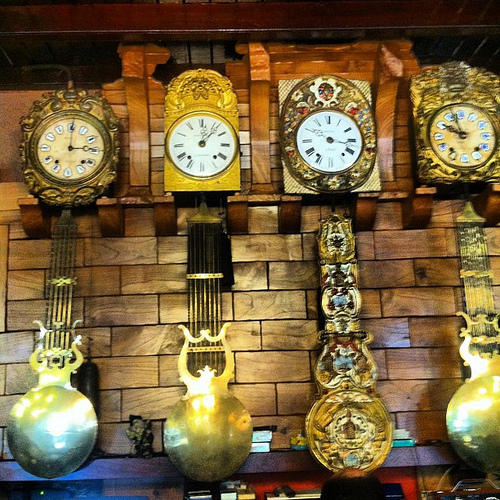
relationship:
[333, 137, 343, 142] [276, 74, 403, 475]
short hand of clock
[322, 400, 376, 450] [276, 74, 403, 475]
images on clock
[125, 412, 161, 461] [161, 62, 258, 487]
figure next to clock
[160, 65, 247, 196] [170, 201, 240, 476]
clock has pendulum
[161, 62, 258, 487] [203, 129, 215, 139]
clock has arm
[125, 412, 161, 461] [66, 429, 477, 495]
figure on shelf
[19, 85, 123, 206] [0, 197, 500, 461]
clock face on wall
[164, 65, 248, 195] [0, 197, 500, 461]
clock on wall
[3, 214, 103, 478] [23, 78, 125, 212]
pendulum hanging from clock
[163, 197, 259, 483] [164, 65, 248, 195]
pendulum hanging from clock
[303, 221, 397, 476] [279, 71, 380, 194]
pendulum hanging from clock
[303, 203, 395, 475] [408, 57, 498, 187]
pendulum hanging from clock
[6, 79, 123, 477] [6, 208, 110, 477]
clock has pendulum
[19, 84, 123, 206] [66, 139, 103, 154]
clock face has black hands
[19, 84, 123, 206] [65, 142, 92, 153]
clock face has hand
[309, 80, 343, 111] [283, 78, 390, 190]
gemstones on clock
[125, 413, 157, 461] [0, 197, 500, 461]
figure on wall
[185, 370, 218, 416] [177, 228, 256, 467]
spot on pendulum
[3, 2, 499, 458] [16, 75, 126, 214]
wall behind clock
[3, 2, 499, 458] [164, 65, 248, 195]
wall behind clock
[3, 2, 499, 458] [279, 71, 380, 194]
wall behind clock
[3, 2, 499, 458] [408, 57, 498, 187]
wall behind clock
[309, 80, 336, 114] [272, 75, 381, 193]
gemstones on clock